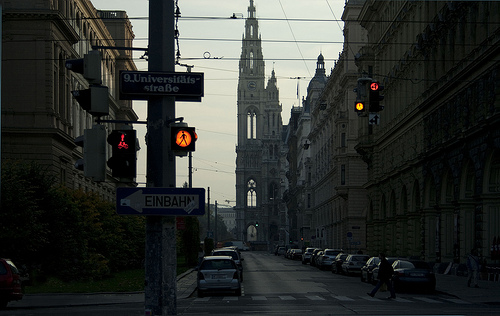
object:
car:
[319, 247, 339, 270]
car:
[359, 254, 381, 277]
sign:
[109, 129, 134, 154]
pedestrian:
[374, 252, 400, 304]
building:
[234, 0, 290, 247]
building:
[285, 0, 500, 269]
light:
[103, 127, 135, 149]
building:
[0, 0, 208, 295]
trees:
[8, 167, 82, 294]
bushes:
[68, 186, 148, 276]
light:
[350, 77, 381, 150]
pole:
[143, 0, 179, 315]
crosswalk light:
[174, 129, 192, 149]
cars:
[301, 244, 324, 264]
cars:
[281, 243, 305, 260]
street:
[0, 246, 499, 316]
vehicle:
[303, 246, 313, 261]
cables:
[0, 7, 500, 74]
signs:
[117, 184, 203, 215]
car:
[338, 250, 370, 277]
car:
[321, 248, 348, 273]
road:
[242, 244, 385, 316]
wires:
[177, 53, 400, 65]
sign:
[113, 71, 206, 103]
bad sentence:
[342, 217, 442, 252]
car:
[389, 259, 419, 280]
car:
[359, 256, 385, 275]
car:
[334, 250, 364, 270]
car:
[195, 254, 245, 290]